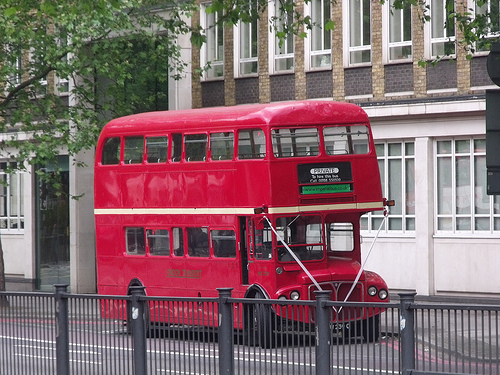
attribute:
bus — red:
[81, 97, 326, 373]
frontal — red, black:
[248, 103, 393, 346]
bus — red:
[91, 100, 391, 340]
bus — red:
[92, 85, 409, 364]